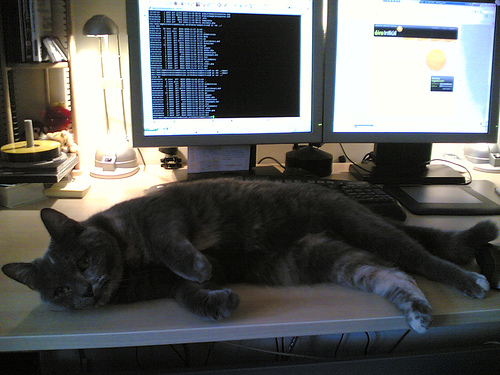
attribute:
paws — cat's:
[196, 282, 247, 317]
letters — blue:
[139, 31, 234, 136]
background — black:
[196, 17, 301, 138]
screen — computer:
[130, 2, 315, 136]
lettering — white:
[146, 9, 233, 124]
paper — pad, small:
[44, 182, 93, 201]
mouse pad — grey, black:
[387, 175, 499, 217]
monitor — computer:
[149, 5, 313, 127]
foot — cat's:
[406, 301, 435, 335]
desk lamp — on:
[78, 11, 139, 181]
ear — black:
[33, 203, 81, 235]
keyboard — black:
[346, 180, 399, 224]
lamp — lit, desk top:
[84, 13, 137, 171]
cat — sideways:
[2, 177, 498, 332]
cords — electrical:
[247, 340, 455, 361]